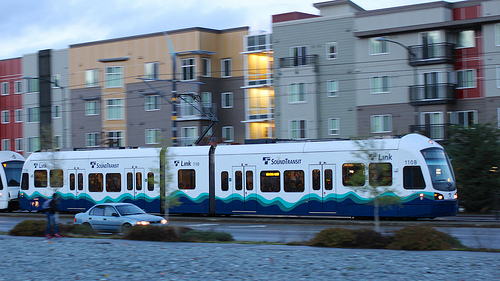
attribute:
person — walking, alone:
[43, 190, 63, 242]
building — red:
[0, 0, 498, 149]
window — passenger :
[267, 163, 308, 203]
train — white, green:
[1, 130, 463, 216]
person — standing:
[38, 189, 61, 239]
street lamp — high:
[365, 33, 410, 47]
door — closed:
[310, 164, 320, 209]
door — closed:
[321, 167, 334, 212]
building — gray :
[269, 0, 484, 144]